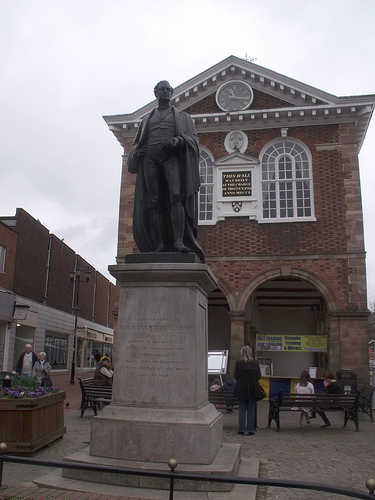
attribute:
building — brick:
[82, 47, 369, 409]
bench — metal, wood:
[266, 389, 363, 433]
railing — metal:
[1, 438, 373, 499]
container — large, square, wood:
[1, 398, 79, 455]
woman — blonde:
[233, 343, 268, 434]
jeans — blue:
[239, 387, 257, 434]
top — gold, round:
[164, 456, 179, 471]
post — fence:
[167, 468, 178, 499]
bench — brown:
[206, 388, 239, 410]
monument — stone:
[59, 264, 257, 491]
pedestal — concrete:
[32, 259, 262, 479]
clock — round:
[211, 79, 260, 112]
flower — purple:
[21, 386, 53, 402]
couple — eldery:
[17, 340, 57, 393]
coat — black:
[233, 357, 266, 403]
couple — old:
[8, 323, 76, 415]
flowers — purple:
[4, 358, 60, 418]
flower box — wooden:
[2, 386, 65, 455]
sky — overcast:
[16, 4, 349, 56]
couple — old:
[14, 342, 52, 387]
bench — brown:
[267, 391, 360, 431]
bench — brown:
[345, 383, 373, 423]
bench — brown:
[77, 376, 116, 414]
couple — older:
[15, 342, 54, 385]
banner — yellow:
[254, 332, 327, 351]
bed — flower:
[7, 382, 77, 452]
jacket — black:
[228, 360, 271, 406]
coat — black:
[232, 362, 265, 400]